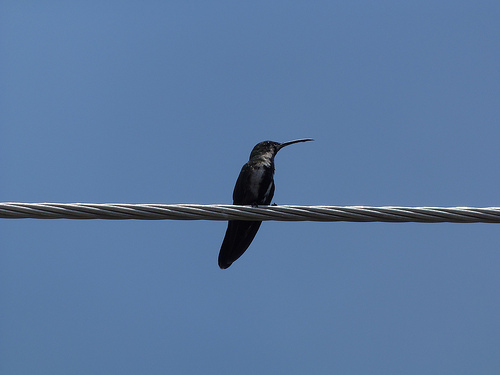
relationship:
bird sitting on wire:
[197, 125, 344, 318] [148, 189, 378, 235]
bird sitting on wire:
[214, 133, 320, 273] [166, 200, 336, 236]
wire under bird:
[3, 205, 496, 224] [214, 133, 320, 273]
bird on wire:
[214, 133, 320, 273] [0, 201, 497, 228]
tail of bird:
[217, 219, 259, 268] [214, 133, 320, 273]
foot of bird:
[251, 193, 263, 213] [210, 130, 322, 270]